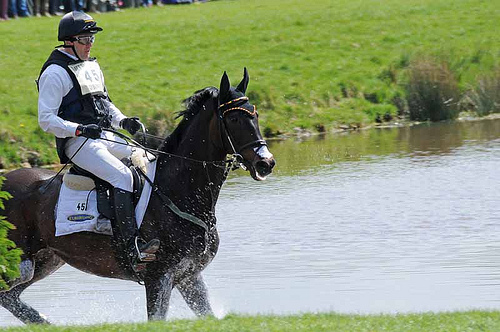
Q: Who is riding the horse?
A: Number 45.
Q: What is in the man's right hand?
A: Riding crop.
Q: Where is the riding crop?
A: In the man's right hand.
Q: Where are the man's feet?
A: In stirrups.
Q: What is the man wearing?
A: Riding outfit.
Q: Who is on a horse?
A: A man.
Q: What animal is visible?
A: Horse.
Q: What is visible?
A: Horse.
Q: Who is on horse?
A: Jockey.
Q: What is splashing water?
A: Horse.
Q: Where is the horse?
A: In grass.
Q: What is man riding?
A: Horse.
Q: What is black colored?
A: Hat.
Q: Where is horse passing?
A: River.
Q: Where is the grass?
A: In field.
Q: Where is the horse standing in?
A: Water.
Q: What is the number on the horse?
A: 45.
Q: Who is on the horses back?
A: Jockey.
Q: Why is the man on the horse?
A: Competition.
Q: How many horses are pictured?
A: 1.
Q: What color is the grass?
A: Green.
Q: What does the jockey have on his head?
A: Helmet.